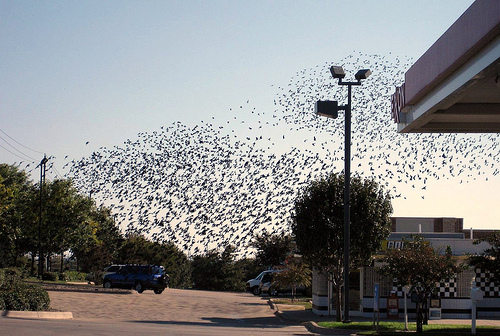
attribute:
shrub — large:
[1, 261, 62, 319]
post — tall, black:
[297, 35, 395, 331]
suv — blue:
[90, 263, 215, 306]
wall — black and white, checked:
[377, 223, 475, 328]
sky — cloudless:
[1, 12, 259, 112]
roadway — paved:
[8, 284, 271, 333]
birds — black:
[52, 59, 355, 282]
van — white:
[237, 264, 309, 304]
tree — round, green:
[292, 164, 402, 298]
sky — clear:
[41, 19, 188, 115]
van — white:
[247, 272, 271, 292]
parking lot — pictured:
[16, 267, 497, 334]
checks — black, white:
[425, 260, 495, 295]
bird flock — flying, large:
[53, 51, 497, 254]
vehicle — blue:
[97, 262, 175, 301]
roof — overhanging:
[385, 3, 498, 149]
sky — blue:
[6, 4, 496, 242]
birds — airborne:
[18, 50, 487, 261]